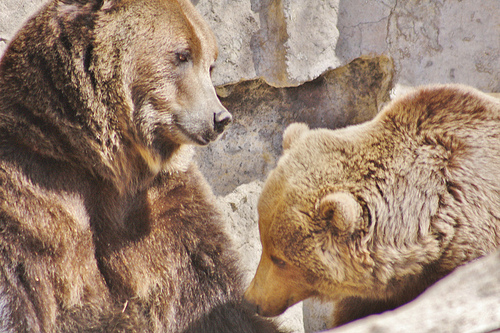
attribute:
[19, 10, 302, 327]
fur — thick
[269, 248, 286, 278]
eye — brown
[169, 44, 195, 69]
eye — brown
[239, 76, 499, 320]
bear — Mature, light brown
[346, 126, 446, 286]
neck — short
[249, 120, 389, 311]
head — up